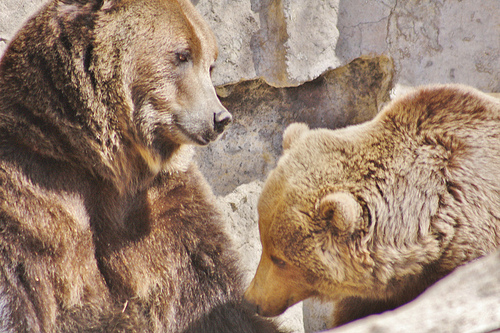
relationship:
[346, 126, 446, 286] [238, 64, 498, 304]
neck of a bear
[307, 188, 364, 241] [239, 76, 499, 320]
ear on bear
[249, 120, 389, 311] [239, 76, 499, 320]
head of bear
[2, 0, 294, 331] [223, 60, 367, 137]
bear at zoo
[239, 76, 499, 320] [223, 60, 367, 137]
bear at zoo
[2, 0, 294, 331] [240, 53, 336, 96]
bear at zoo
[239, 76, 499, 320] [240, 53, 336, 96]
bear at zoo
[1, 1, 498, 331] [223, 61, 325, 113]
rock face in background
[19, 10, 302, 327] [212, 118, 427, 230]
fur on bear